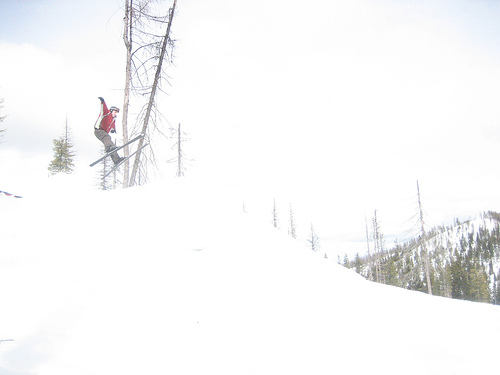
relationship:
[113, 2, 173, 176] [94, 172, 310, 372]
tree over hill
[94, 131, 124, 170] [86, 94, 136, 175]
pants on skier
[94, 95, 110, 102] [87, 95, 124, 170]
glove on man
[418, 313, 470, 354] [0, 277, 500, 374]
white snow on ground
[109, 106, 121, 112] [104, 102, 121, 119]
goggles on mans head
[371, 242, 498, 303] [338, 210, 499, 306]
trees on mountain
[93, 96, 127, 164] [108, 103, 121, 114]
man wearing helmet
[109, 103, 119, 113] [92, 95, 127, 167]
helmet on person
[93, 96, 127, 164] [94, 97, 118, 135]
man wearing coat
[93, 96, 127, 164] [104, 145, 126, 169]
man wearing boots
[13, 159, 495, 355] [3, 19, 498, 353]
snow on mountain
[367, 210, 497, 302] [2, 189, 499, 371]
trees on snow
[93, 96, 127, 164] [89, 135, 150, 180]
man on skis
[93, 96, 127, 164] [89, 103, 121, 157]
man wears snowsuit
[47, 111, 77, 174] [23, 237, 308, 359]
tree on snow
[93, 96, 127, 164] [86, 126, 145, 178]
man wearing pants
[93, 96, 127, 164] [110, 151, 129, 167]
man wearing boot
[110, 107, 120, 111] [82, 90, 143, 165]
goggles are on skier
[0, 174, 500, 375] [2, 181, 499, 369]
snow on hill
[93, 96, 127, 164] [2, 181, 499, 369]
man jumping hill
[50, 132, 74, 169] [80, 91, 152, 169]
tree behind skier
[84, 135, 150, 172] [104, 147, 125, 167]
skis are on feet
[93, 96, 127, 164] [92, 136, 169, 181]
man wearing skis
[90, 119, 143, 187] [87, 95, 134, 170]
tree beside man